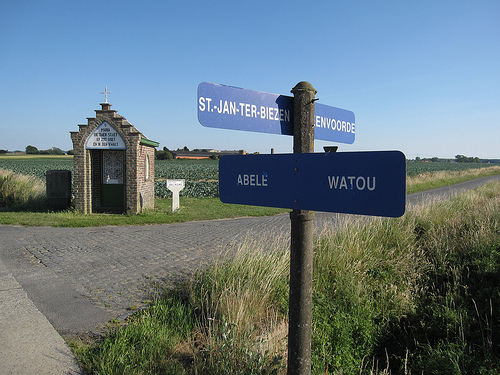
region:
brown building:
[55, 106, 153, 224]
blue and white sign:
[180, 72, 380, 154]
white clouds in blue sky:
[8, 11, 58, 69]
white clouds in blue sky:
[70, 62, 108, 76]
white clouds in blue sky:
[122, 19, 174, 69]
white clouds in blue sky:
[417, 18, 489, 88]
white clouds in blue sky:
[404, 48, 475, 112]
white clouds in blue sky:
[318, 19, 378, 61]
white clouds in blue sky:
[231, 25, 261, 52]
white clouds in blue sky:
[138, 13, 178, 90]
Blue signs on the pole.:
[183, 49, 447, 373]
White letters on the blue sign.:
[172, 122, 425, 229]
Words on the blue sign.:
[189, 130, 419, 242]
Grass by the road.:
[192, 219, 287, 327]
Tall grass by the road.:
[186, 234, 275, 362]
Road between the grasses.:
[68, 177, 214, 356]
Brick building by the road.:
[46, 90, 176, 273]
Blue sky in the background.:
[387, 38, 495, 191]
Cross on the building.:
[73, 59, 135, 117]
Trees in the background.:
[407, 137, 485, 193]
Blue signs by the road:
[193, 84, 405, 216]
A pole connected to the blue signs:
[288, 83, 312, 373]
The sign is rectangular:
[221, 149, 406, 216]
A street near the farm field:
[1, 174, 498, 355]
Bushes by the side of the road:
[1, 168, 48, 208]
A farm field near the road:
[0, 159, 488, 200]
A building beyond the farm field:
[169, 148, 235, 159]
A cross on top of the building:
[97, 88, 113, 103]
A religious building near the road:
[72, 88, 156, 215]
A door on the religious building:
[101, 151, 126, 209]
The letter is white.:
[196, 94, 205, 114]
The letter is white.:
[203, 95, 213, 112]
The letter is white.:
[216, 92, 224, 116]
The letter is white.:
[241, 171, 248, 189]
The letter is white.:
[248, 170, 257, 187]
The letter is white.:
[323, 170, 340, 192]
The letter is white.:
[336, 168, 348, 194]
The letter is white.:
[354, 171, 366, 195]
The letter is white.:
[363, 170, 378, 192]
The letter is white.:
[249, 101, 257, 122]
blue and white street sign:
[194, 80, 359, 145]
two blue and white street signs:
[195, 75, 410, 218]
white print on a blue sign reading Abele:
[233, 171, 270, 188]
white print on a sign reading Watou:
[323, 172, 377, 192]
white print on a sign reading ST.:
[198, 95, 215, 113]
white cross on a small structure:
[98, 83, 115, 104]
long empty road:
[3, 165, 499, 374]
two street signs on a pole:
[195, 79, 410, 374]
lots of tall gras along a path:
[70, 175, 497, 374]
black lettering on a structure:
[85, 125, 124, 149]